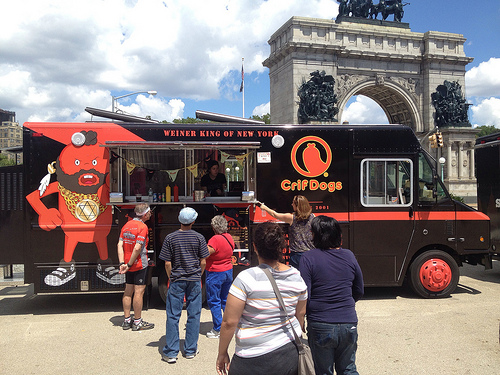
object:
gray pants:
[228, 336, 302, 374]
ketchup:
[173, 184, 178, 202]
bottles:
[166, 184, 172, 202]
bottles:
[148, 188, 153, 197]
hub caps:
[419, 258, 453, 292]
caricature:
[25, 130, 126, 287]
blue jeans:
[163, 280, 203, 357]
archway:
[332, 73, 425, 132]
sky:
[0, 0, 499, 121]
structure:
[260, 0, 483, 210]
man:
[117, 202, 152, 331]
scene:
[0, 0, 500, 375]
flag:
[240, 82, 243, 92]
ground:
[0, 259, 500, 375]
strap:
[258, 264, 304, 351]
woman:
[214, 219, 309, 374]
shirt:
[228, 263, 308, 359]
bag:
[258, 264, 317, 374]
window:
[110, 145, 256, 205]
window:
[360, 157, 414, 207]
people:
[117, 195, 366, 375]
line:
[252, 211, 490, 225]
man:
[159, 206, 210, 364]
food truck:
[0, 106, 493, 310]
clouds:
[0, 0, 500, 131]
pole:
[242, 57, 244, 118]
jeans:
[306, 319, 358, 374]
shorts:
[125, 266, 148, 284]